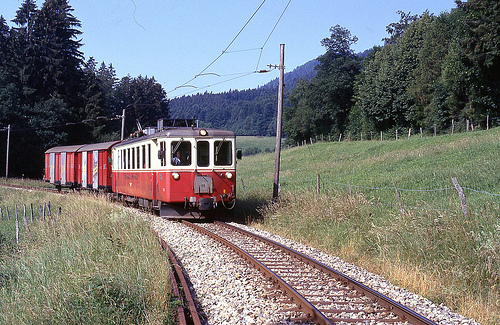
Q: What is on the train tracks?
A: A red and white train.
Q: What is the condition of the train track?
A: Rusty.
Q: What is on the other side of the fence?
A: Green trees.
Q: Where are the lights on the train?
A: The front of the train.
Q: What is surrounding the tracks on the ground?
A: Gravel.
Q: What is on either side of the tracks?
A: Grass.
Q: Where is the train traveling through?
A: The countryside.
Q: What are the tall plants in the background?
A: Evergreen trees.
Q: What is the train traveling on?
A: Train tracks.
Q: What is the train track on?
A: Rocks.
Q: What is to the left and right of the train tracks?
A: Grassy fields.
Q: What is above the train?
A: Power lines.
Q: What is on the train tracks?
A: Red and white train.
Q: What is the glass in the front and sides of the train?
A: Windows.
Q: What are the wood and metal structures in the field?
A: Fences.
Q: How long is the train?
A: Three compartments long.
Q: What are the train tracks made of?
A: Metal.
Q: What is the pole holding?
A: Wires.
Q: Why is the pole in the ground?
A: To hold wires.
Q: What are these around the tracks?
A: Rocks.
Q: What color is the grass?
A: Green.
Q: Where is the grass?
A: Next to the train tracks.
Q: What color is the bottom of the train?
A: Red.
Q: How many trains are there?
A: One.